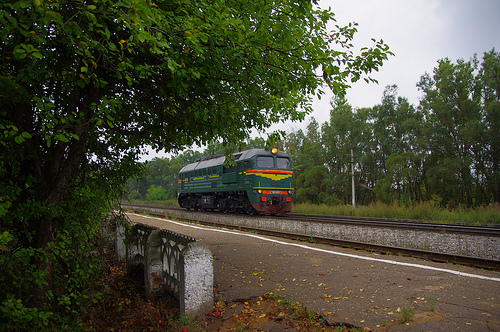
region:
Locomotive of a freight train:
[170, 140, 305, 220]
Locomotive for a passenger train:
[160, 138, 316, 218]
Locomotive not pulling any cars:
[147, 142, 322, 223]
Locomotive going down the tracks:
[171, 137, 302, 223]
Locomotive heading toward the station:
[170, 135, 316, 235]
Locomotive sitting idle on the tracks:
[163, 137, 303, 230]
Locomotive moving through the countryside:
[163, 136, 313, 236]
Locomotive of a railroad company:
[165, 127, 310, 242]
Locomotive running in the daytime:
[168, 140, 313, 225]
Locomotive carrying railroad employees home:
[165, 138, 317, 227]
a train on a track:
[93, 67, 376, 269]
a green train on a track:
[107, 95, 360, 295]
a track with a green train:
[158, 106, 414, 291]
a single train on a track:
[111, 95, 415, 280]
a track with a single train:
[119, 47, 426, 274]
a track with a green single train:
[110, 122, 474, 255]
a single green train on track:
[153, 78, 496, 285]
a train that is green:
[143, 50, 390, 312]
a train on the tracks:
[130, 100, 342, 245]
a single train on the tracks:
[147, 97, 352, 266]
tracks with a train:
[116, 77, 383, 286]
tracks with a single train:
[130, 105, 339, 253]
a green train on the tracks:
[132, 90, 312, 242]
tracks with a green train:
[162, 85, 429, 285]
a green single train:
[171, 79, 426, 281]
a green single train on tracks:
[118, 57, 389, 309]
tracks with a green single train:
[132, 87, 359, 329]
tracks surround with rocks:
[196, 99, 499, 316]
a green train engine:
[161, 146, 297, 222]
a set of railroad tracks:
[123, 191, 495, 236]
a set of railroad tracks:
[117, 215, 490, 269]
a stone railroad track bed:
[121, 198, 495, 260]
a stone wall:
[105, 217, 205, 312]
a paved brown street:
[117, 206, 495, 330]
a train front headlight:
[267, 142, 277, 156]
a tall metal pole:
[342, 137, 360, 202]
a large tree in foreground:
[4, 9, 357, 239]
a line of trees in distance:
[123, 42, 492, 209]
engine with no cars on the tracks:
[174, 146, 298, 218]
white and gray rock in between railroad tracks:
[299, 210, 493, 263]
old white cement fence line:
[101, 209, 216, 323]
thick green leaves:
[128, 13, 232, 76]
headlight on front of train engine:
[267, 143, 281, 156]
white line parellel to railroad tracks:
[279, 237, 475, 300]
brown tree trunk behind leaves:
[26, 160, 65, 314]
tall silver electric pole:
[344, 144, 359, 217]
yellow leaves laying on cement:
[244, 261, 280, 292]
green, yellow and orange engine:
[174, 144, 296, 222]